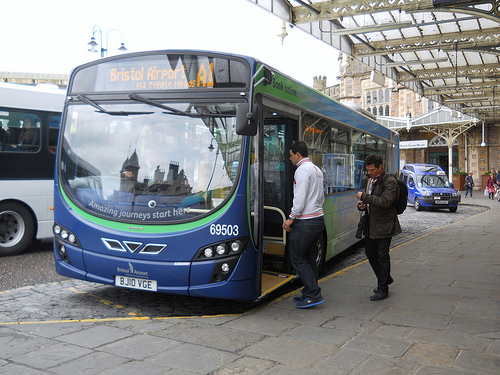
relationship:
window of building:
[362, 88, 374, 105] [313, 57, 495, 204]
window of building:
[370, 88, 379, 103] [313, 57, 495, 204]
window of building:
[382, 87, 390, 102] [313, 57, 495, 204]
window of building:
[378, 104, 386, 118] [313, 57, 495, 204]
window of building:
[382, 104, 392, 116] [313, 57, 495, 204]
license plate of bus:
[114, 275, 158, 290] [50, 35, 410, 313]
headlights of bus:
[51, 221, 78, 245] [50, 35, 410, 313]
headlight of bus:
[53, 222, 60, 236] [56, 52, 406, 293]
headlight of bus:
[60, 230, 67, 237] [56, 52, 406, 293]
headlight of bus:
[66, 235, 76, 244] [56, 52, 406, 293]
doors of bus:
[258, 110, 293, 269] [56, 52, 406, 293]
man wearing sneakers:
[282, 141, 328, 308] [295, 291, 328, 308]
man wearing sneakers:
[356, 153, 402, 300] [362, 278, 406, 303]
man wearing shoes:
[353, 151, 408, 301] [362, 282, 397, 301]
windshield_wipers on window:
[67, 92, 248, 123] [59, 97, 243, 221]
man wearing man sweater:
[281, 147, 329, 312] [288, 157, 325, 219]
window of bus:
[59, 97, 243, 221] [56, 52, 406, 293]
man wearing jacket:
[353, 151, 408, 301] [365, 177, 403, 239]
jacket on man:
[360, 172, 403, 242] [353, 152, 402, 301]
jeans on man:
[281, 202, 325, 297] [262, 130, 341, 335]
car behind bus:
[393, 157, 484, 215] [50, 35, 410, 313]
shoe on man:
[291, 290, 327, 314] [279, 124, 330, 328]